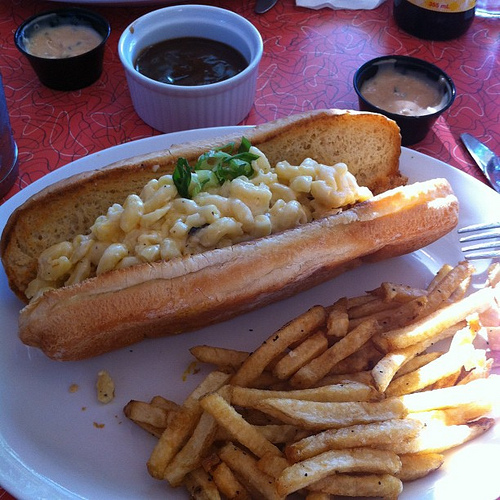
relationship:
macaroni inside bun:
[25, 145, 374, 298] [1, 108, 459, 361]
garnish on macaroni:
[172, 136, 260, 200] [25, 145, 374, 298]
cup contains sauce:
[15, 10, 111, 91] [24, 24, 103, 59]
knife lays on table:
[460, 132, 500, 194] [2, 0, 500, 207]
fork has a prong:
[457, 220, 499, 261] [458, 220, 500, 234]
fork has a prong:
[457, 220, 499, 261] [459, 230, 499, 243]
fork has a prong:
[457, 220, 499, 261] [461, 240, 500, 252]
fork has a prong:
[457, 220, 499, 261] [464, 249, 500, 261]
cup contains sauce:
[117, 4, 263, 133] [132, 36, 250, 87]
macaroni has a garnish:
[25, 145, 374, 298] [172, 136, 260, 200]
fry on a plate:
[225, 304, 328, 387] [0, 125, 499, 500]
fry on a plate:
[273, 330, 329, 379] [0, 125, 499, 500]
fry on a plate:
[288, 315, 382, 390] [0, 125, 499, 500]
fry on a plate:
[326, 296, 349, 337] [0, 125, 499, 500]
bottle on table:
[392, 0, 476, 40] [2, 0, 500, 207]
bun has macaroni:
[1, 108, 459, 361] [25, 145, 374, 298]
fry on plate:
[225, 304, 328, 387] [0, 125, 499, 500]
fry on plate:
[273, 330, 329, 379] [0, 125, 499, 500]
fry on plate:
[288, 315, 382, 390] [0, 125, 499, 500]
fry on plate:
[326, 296, 349, 337] [0, 125, 499, 500]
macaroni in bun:
[25, 145, 374, 298] [1, 108, 459, 361]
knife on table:
[460, 132, 500, 194] [2, 0, 500, 207]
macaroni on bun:
[25, 145, 374, 298] [1, 108, 459, 361]